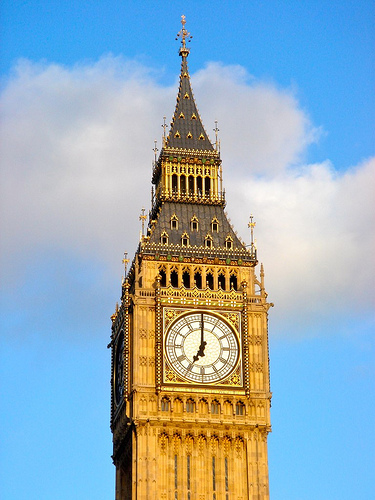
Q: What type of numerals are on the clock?
A: Roman.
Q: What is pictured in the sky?
A: Clouds.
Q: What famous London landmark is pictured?
A: Big Ben.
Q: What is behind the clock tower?
A: Clouds.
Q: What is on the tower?
A: A clock.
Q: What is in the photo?
A: A clock.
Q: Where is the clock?
A: On the building.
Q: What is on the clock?
A: Hands.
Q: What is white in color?
A: The clouds.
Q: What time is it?
A: 7:00.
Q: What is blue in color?
A: The sky.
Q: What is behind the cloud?
A: The blue sky.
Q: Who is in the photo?
A: No people.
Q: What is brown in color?
A: The clock tower.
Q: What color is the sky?
A: Blue.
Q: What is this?
A: Clock tower.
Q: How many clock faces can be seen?
A: Two.